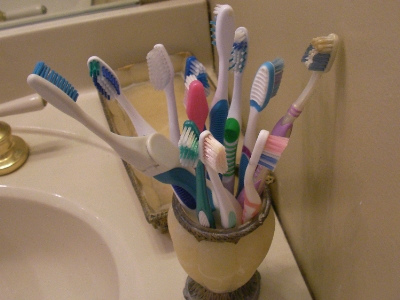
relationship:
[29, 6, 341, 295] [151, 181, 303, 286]
toothbrushes in cup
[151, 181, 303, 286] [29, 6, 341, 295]
cup holding toothbrushes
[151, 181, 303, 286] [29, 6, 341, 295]
cup holds toothbrushes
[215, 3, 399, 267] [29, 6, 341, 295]
wall beside toothbrushes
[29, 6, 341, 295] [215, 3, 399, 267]
toothbrushes near wall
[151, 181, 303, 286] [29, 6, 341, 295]
cup under toothbrushes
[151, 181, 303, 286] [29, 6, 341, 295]
cup below toothbrushes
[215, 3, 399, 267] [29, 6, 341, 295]
wall close to toothbrushes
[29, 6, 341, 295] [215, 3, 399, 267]
toothbrushes close with wall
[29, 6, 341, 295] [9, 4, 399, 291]
toothbrushes in household